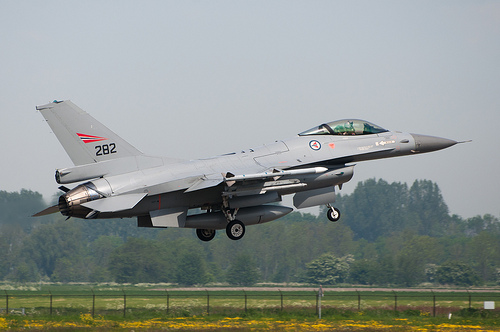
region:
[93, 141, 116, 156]
black numbers saying 282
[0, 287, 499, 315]
black metal fence with barb wire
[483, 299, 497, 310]
small rectangle white sign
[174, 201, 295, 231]
bright grey bomb asking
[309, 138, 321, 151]
round red and white insignia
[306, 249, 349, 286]
large green bush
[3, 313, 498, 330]
grass field with yellow flowers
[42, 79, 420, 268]
grey plane taking off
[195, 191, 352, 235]
black and white wheels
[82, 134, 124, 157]
black number on tail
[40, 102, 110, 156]
grey and red tail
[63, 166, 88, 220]
copper afterburner near tail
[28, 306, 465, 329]
green and yellow grasses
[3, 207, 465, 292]
thick row of trees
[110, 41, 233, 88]
grey and cloudy sky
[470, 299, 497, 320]
white sign on fence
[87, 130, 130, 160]
numbers 282 on the plane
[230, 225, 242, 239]
the wheels on the airplane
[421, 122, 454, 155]
the grey front of the airplane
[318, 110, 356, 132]
the pilot of the plane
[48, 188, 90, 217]
the back end of the jet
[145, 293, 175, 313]
the brown fence on the ground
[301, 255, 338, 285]
the green tree in the distance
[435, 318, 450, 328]
the yellow flowers on the ground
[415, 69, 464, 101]
the big blue sky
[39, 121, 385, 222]
the jet number 282 taking off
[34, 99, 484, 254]
jet is in flight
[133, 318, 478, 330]
tiny yellow flowers growing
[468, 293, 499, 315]
white sign on the fence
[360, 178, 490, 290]
lush green trees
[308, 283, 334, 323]
pole next to fence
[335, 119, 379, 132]
person has a helmet on for safety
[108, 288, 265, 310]
tiny white flowers growing on the other side of the fence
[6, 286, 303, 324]
fence haas flowers growing on both sides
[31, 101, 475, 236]
a jet in flight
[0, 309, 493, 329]
yellow flowers on grass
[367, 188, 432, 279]
trees on the land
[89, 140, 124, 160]
number of jet written in black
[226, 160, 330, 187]
wing on right side of jet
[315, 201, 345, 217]
front wheel on jet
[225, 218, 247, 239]
right wheel on jet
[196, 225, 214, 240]
left wheel on the jet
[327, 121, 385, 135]
cockpit on the jet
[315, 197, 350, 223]
wheel on a plane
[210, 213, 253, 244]
wheel on a plane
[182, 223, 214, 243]
wheel on a plane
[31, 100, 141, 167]
wing on a plane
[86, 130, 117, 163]
number on a plane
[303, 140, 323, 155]
decal on a plane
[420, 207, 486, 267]
trees near a field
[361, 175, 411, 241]
trees near a field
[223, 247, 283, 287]
tree near a field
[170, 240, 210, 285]
tree near a field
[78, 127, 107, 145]
a logo on a jet plane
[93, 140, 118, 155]
three numbers on a grey jet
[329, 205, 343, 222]
the black and white wheel on a plane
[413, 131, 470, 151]
the nose of a jet plane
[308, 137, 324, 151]
a blue white and red logo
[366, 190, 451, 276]
the forest in the back is green and far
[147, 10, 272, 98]
a hazy cloudy sky